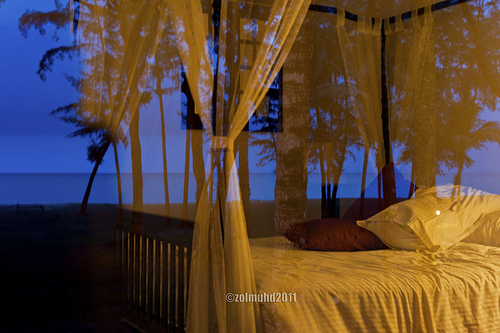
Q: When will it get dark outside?
A: After the sun goes down.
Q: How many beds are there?
A: One.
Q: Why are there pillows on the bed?
A: For the man or woman to lay their heads on while sleeping.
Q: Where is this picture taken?
A: At a bedroom.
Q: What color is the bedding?
A: White.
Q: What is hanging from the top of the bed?
A: A canopy.